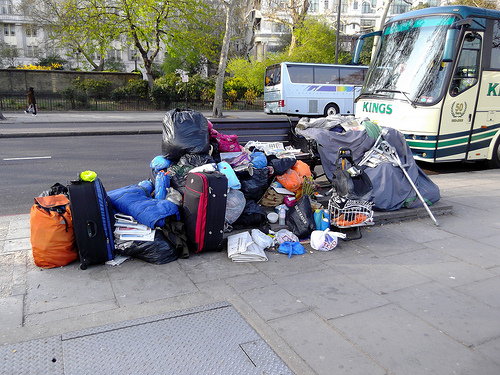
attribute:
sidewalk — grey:
[0, 168, 499, 373]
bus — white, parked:
[265, 62, 369, 119]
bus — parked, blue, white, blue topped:
[356, 3, 498, 168]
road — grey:
[0, 110, 363, 216]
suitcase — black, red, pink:
[183, 169, 230, 255]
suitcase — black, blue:
[68, 174, 117, 276]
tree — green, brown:
[46, 2, 225, 88]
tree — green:
[228, 13, 347, 97]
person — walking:
[25, 85, 38, 117]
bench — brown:
[207, 118, 316, 179]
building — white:
[0, 1, 210, 83]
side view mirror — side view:
[441, 27, 459, 63]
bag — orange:
[29, 193, 78, 270]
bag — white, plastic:
[309, 227, 347, 254]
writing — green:
[362, 102, 393, 116]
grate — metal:
[0, 302, 296, 374]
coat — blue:
[106, 185, 182, 230]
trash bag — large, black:
[158, 108, 212, 162]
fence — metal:
[0, 93, 265, 114]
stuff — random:
[29, 172, 190, 266]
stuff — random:
[219, 150, 318, 254]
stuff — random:
[293, 118, 442, 225]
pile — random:
[29, 110, 436, 264]